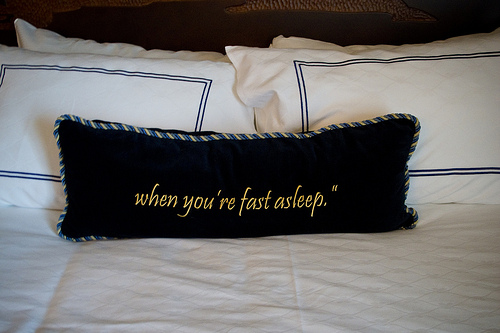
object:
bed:
[0, 0, 500, 333]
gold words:
[135, 183, 339, 218]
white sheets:
[0, 204, 499, 333]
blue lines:
[0, 65, 213, 183]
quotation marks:
[332, 185, 338, 192]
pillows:
[1, 17, 499, 211]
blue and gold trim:
[53, 112, 422, 243]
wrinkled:
[162, 257, 296, 313]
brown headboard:
[0, 0, 500, 56]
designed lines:
[286, 235, 305, 331]